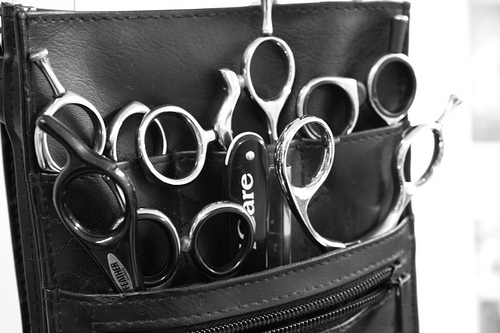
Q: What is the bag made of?
A: Leather.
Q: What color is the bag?
A: Black.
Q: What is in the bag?
A: Tools.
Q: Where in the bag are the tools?
A: Side pockets.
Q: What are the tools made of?
A: Metals.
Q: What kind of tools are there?
A: Scissors.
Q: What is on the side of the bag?
A: Zipper.